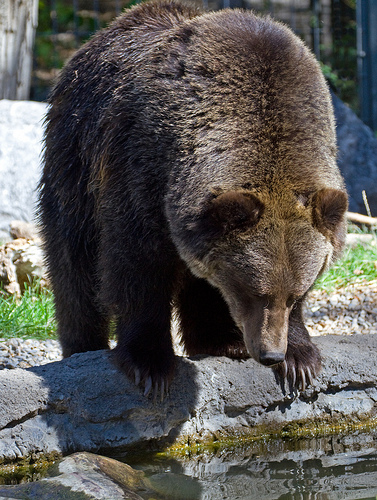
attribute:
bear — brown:
[41, 6, 344, 402]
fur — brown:
[83, 39, 298, 149]